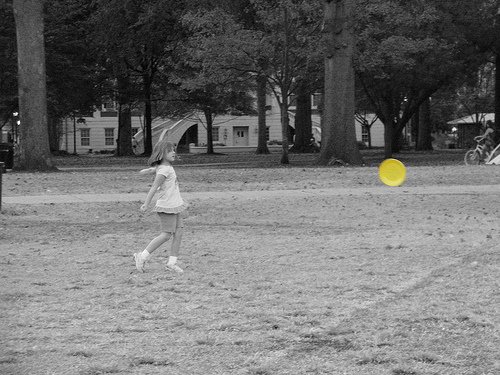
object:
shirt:
[150, 164, 188, 214]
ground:
[80, 250, 246, 369]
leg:
[169, 213, 184, 263]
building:
[2, 51, 403, 176]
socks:
[140, 249, 178, 265]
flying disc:
[378, 158, 406, 186]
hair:
[147, 140, 179, 168]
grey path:
[4, 184, 138, 208]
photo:
[0, 0, 500, 373]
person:
[473, 120, 499, 162]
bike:
[464, 137, 500, 166]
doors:
[233, 126, 248, 144]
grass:
[207, 281, 427, 367]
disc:
[379, 158, 406, 187]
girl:
[133, 141, 187, 274]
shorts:
[157, 212, 184, 233]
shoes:
[133, 252, 147, 273]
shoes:
[162, 264, 183, 273]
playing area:
[152, 272, 459, 373]